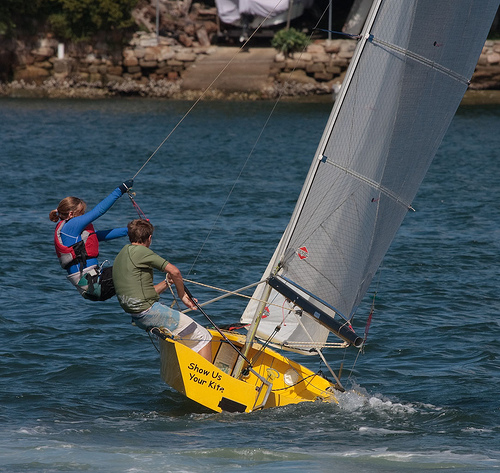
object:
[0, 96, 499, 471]
pond